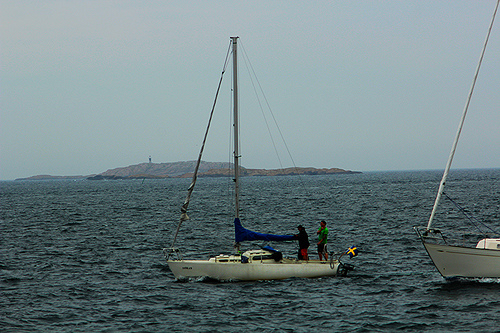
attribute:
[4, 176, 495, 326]
water — rippled, rough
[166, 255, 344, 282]
boat — white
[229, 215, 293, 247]
flag — blue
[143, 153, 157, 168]
lighthouse — distant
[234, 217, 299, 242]
sail — blue, rolled up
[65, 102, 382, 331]
boat — a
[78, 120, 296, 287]
boat — the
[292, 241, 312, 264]
something — red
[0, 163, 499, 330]
water — the